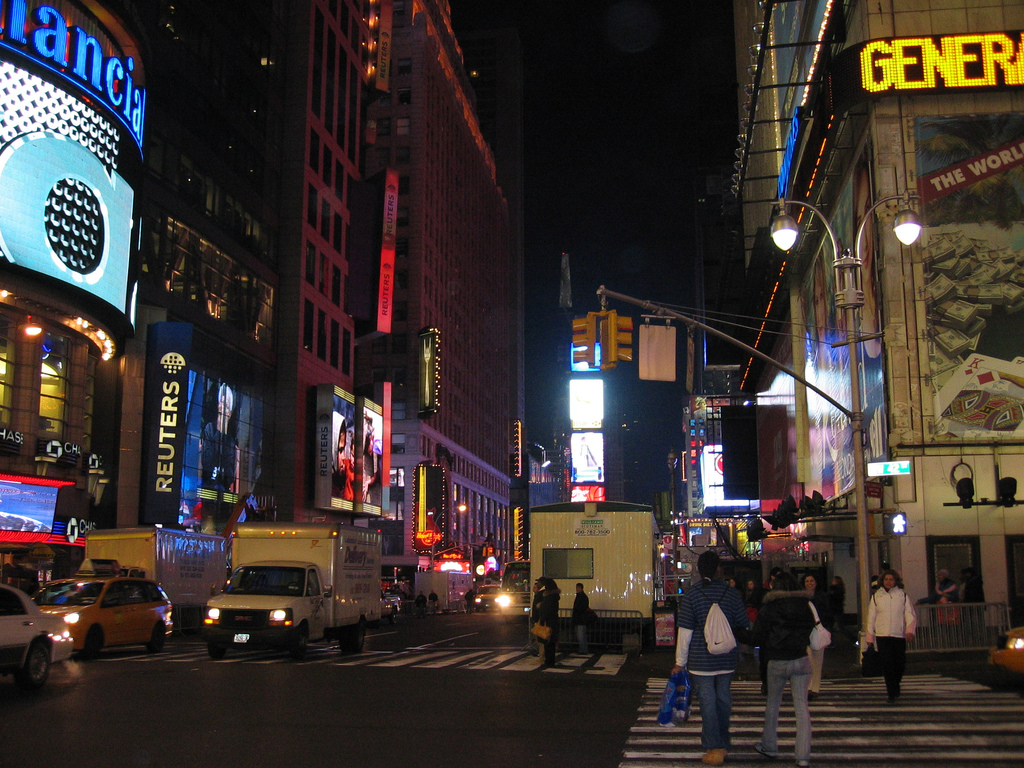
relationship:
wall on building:
[4, 263, 305, 646] [2, 6, 361, 637]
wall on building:
[15, 269, 392, 643] [6, 3, 410, 632]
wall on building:
[870, 99, 1015, 650] [788, 12, 1022, 661]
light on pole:
[771, 211, 795, 246] [827, 258, 879, 658]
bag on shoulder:
[808, 604, 834, 648] [758, 589, 815, 657]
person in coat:
[860, 572, 919, 696] [860, 587, 919, 639]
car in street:
[26, 569, 174, 658] [10, 554, 1022, 760]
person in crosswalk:
[525, 574, 567, 668] [106, 608, 657, 686]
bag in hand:
[656, 669, 698, 722] [665, 664, 687, 682]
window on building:
[306, 300, 335, 365] [300, 4, 359, 394]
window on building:
[315, 312, 331, 369] [300, 4, 359, 394]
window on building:
[330, 317, 346, 372] [285, 1, 353, 503]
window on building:
[342, 326, 351, 377] [296, 16, 357, 505]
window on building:
[330, 267, 348, 311] [283, 1, 363, 513]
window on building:
[313, 246, 333, 301] [296, 23, 372, 518]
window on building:
[315, 248, 337, 292] [158, 17, 364, 547]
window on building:
[302, 181, 318, 216] [246, 205, 372, 417]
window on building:
[289, 203, 326, 212] [264, 151, 411, 355]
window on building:
[316, 200, 334, 229] [287, 205, 359, 312]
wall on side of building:
[80, 347, 202, 559] [35, 192, 368, 674]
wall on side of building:
[67, 306, 232, 616] [11, 438, 461, 618]